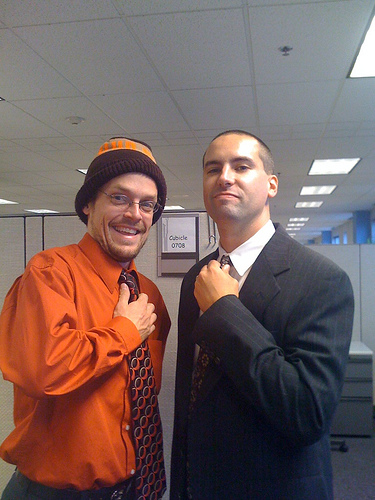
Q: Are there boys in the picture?
A: No, there are no boys.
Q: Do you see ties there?
A: Yes, there is a tie.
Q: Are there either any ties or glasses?
A: Yes, there is a tie.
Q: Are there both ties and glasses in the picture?
A: Yes, there are both a tie and glasses.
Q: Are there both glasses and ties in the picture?
A: Yes, there are both a tie and glasses.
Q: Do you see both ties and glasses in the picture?
A: Yes, there are both a tie and glasses.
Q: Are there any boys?
A: No, there are no boys.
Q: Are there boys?
A: No, there are no boys.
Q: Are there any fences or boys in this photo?
A: No, there are no boys or fences.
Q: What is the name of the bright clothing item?
A: The clothing item is a shirt.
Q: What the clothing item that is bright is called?
A: The clothing item is a shirt.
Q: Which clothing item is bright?
A: The clothing item is a shirt.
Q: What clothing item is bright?
A: The clothing item is a shirt.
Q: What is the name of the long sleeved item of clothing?
A: The clothing item is a shirt.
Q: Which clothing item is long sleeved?
A: The clothing item is a shirt.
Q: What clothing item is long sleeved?
A: The clothing item is a shirt.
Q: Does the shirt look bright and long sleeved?
A: Yes, the shirt is bright and long sleeved.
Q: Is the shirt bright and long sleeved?
A: Yes, the shirt is bright and long sleeved.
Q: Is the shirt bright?
A: Yes, the shirt is bright.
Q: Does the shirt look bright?
A: Yes, the shirt is bright.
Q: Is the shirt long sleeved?
A: Yes, the shirt is long sleeved.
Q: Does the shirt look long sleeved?
A: Yes, the shirt is long sleeved.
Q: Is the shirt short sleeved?
A: No, the shirt is long sleeved.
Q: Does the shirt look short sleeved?
A: No, the shirt is long sleeved.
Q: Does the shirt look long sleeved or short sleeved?
A: The shirt is long sleeved.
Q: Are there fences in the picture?
A: No, there are no fences.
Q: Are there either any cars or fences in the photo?
A: No, there are no fences or cars.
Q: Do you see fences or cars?
A: No, there are no fences or cars.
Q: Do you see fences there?
A: No, there are no fences.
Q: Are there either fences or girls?
A: No, there are no fences or girls.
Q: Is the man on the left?
A: Yes, the man is on the left of the image.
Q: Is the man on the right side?
A: No, the man is on the left of the image.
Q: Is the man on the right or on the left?
A: The man is on the left of the image.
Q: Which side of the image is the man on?
A: The man is on the left of the image.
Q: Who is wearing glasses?
A: The man is wearing glasses.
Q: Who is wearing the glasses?
A: The man is wearing glasses.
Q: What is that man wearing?
A: The man is wearing glasses.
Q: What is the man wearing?
A: The man is wearing glasses.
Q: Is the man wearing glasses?
A: Yes, the man is wearing glasses.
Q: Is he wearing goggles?
A: No, the man is wearing glasses.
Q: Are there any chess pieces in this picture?
A: No, there are no chess pieces.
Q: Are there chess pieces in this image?
A: No, there are no chess pieces.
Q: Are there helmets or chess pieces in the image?
A: No, there are no chess pieces or helmets.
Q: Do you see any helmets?
A: No, there are no helmets.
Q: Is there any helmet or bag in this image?
A: No, there are no helmets or bags.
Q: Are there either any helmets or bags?
A: No, there are no helmets or bags.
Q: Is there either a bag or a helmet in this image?
A: No, there are no helmets or bags.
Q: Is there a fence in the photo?
A: No, there are no fences.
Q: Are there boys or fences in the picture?
A: No, there are no fences or boys.